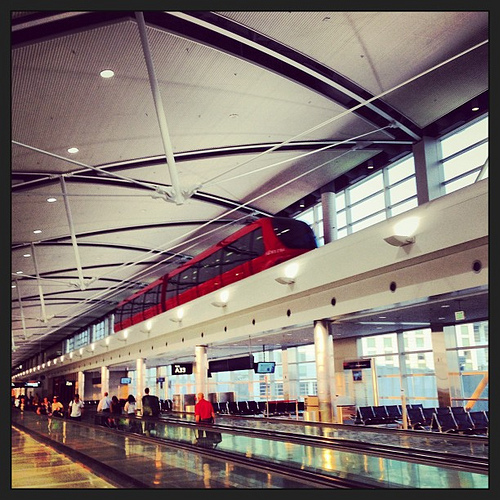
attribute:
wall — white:
[307, 230, 383, 291]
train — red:
[15, 208, 318, 300]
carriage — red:
[109, 212, 318, 335]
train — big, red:
[67, 211, 349, 351]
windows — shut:
[363, 334, 496, 422]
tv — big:
[211, 326, 328, 431]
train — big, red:
[5, 179, 340, 356]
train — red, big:
[108, 207, 311, 327]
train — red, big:
[113, 208, 301, 346]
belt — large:
[8, 412, 488, 475]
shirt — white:
[173, 382, 221, 422]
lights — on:
[269, 221, 419, 286]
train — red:
[11, 214, 315, 375]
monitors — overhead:
[120, 361, 275, 383]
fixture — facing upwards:
[275, 269, 295, 288]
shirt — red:
[195, 399, 215, 424]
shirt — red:
[189, 395, 216, 420]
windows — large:
[232, 323, 477, 413]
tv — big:
[255, 361, 277, 374]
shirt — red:
[193, 400, 212, 420]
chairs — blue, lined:
[204, 395, 491, 433]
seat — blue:
[359, 405, 384, 425]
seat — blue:
[406, 406, 428, 431]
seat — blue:
[432, 410, 461, 434]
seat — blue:
[371, 405, 400, 427]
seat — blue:
[421, 408, 437, 425]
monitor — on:
[255, 358, 276, 378]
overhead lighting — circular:
[45, 189, 137, 296]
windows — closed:
[316, 160, 460, 248]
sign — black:
[155, 358, 195, 377]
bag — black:
[189, 428, 213, 449]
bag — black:
[209, 423, 223, 442]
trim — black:
[328, 136, 420, 196]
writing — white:
[170, 366, 187, 376]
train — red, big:
[111, 216, 316, 336]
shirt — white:
[64, 398, 83, 416]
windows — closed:
[117, 230, 268, 309]